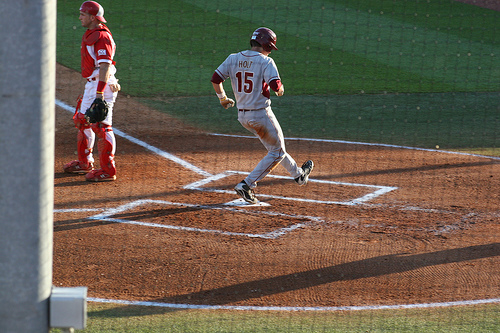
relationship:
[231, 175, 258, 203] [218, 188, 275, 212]
foot on bases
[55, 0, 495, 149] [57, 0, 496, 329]
grass in baseball field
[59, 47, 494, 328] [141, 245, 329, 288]
diamond in dirt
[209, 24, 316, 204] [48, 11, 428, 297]
player in action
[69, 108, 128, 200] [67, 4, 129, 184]
shin pads in player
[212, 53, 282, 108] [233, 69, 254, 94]
jersey has number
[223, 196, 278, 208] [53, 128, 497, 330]
plate on soil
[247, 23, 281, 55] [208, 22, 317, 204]
helmet worn by player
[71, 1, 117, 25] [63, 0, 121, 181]
helmet worn by baseball catcher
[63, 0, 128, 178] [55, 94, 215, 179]
baseball catcher standing on sideline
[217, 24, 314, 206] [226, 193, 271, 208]
player running to plate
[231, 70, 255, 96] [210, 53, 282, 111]
number on back of jersey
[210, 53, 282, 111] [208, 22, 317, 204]
jersey on player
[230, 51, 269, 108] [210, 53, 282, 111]
back on jersey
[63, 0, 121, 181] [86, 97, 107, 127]
baseball catcher holding baseball mitt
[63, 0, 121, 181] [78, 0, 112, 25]
baseball catcher wearing hat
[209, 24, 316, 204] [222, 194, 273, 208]
player touching bases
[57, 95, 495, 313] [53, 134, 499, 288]
marks on dirt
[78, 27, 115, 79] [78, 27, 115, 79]
red shirt with red shirt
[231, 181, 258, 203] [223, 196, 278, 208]
foot on plate